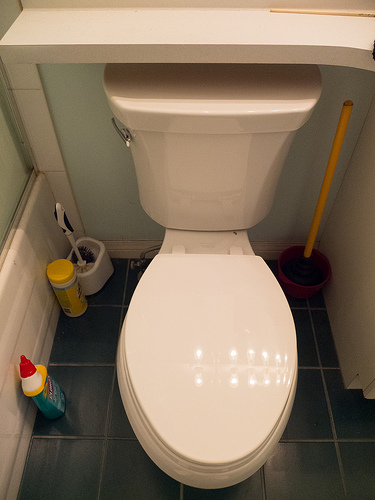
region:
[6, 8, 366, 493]
counter over toilet tank attached to toilet bowl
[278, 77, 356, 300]
wooden-handled plunger in corner of bathroom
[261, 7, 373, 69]
yellow chopstick on top of white counter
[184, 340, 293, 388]
round white lights reflecting off closed white lid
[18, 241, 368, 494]
square black tiles covering floor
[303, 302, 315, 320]
Small white groutline on the floor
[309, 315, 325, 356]
Small white groutline on the floor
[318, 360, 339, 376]
Small white groutline on the floor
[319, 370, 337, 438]
Small white groutline on the floor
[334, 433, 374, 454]
Small white groutline on the floor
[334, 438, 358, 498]
Small white groutline on the floor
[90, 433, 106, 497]
Small white groutline on the floor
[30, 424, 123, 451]
Small white groutline on the floor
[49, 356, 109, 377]
Small white groutline on the floor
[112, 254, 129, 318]
Small white groutline on the floor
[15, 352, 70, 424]
Chemical cleaner for the toilet.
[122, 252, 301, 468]
A longer toilet lid.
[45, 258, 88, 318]
Disposable chemical wipes for cleaning the bathroom.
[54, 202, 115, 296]
Toilet bowl brush inside of stand.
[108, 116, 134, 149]
Toilet handle for flushing the water and waste mater down the drain.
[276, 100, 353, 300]
Plunger for getting clogs undone in the toilet.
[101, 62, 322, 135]
Toilet tank lid cover.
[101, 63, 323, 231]
Toilet water reservoir for flushing toilet.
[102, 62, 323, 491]
White toilet elongated. Also called the Crapper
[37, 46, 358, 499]
A white bathroom toilet.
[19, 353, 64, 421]
A cleaner bottle with a red cap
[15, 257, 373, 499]
A floor with tiles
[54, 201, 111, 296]
A toilet brush and container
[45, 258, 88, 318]
A container of cleaning wipes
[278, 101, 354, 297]
A toilet plunger in corner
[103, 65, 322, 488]
A white toilet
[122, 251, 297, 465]
A white toilet lid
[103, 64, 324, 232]
A white toliet tank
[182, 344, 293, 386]
Lights reflecting off toilet lid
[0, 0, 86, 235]
White tiles on wall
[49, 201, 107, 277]
Blue and white toilet bush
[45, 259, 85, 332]
Yellow bottle on floor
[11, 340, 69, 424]
Bottle on the floor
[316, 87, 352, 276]
Yellow handle next to the wall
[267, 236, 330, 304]
Black and yellow plunger in bowl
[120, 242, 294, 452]
White toilet seat on toilet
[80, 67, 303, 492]
White toilet on the floor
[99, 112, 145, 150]
Chrome toilet flusher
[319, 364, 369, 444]
Blue tile on the floor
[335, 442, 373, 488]
Blue tile on the floor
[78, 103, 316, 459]
white toilet in bathroom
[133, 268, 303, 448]
toilet lid is lowered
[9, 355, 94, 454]
green bottle of cleaner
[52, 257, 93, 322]
yellow bottle of wipes